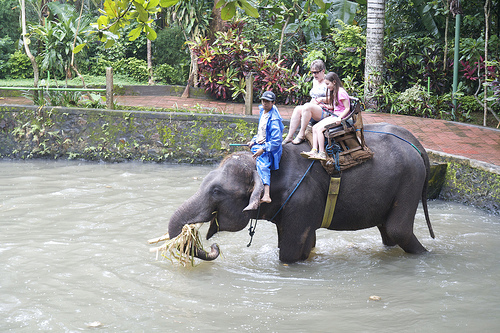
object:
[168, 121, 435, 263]
elephant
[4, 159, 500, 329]
water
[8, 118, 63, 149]
plants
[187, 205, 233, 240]
mouth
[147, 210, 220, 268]
trunk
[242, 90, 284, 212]
man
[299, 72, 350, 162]
girl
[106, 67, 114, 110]
post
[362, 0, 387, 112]
palm tree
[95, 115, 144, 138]
moss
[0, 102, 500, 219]
wall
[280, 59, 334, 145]
tourists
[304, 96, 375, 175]
seat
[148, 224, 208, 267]
leaves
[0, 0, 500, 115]
forest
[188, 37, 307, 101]
plant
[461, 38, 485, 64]
leaf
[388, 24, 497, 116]
bush